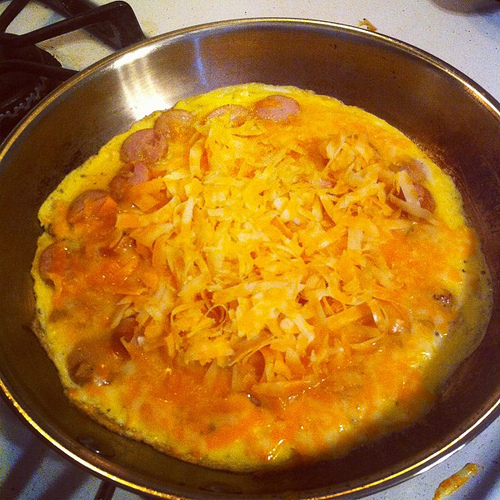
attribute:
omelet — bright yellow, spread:
[32, 82, 477, 474]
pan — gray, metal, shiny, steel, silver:
[0, 17, 499, 498]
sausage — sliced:
[257, 94, 301, 118]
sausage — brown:
[162, 114, 198, 141]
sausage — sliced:
[68, 189, 109, 217]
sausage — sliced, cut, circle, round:
[120, 129, 156, 158]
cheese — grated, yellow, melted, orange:
[120, 119, 434, 392]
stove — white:
[0, 0, 497, 499]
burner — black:
[0, 0, 145, 142]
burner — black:
[93, 478, 111, 498]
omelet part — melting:
[435, 463, 476, 499]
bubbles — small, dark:
[58, 170, 103, 188]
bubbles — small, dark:
[460, 261, 495, 307]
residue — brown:
[149, 489, 183, 499]